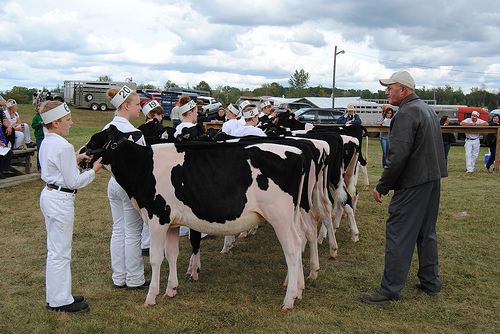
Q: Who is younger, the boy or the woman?
A: The boy is younger than the woman.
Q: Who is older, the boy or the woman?
A: The woman is older than the boy.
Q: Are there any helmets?
A: No, there are no helmets.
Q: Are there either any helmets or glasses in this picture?
A: No, there are no helmets or glasses.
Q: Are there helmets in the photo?
A: No, there are no helmets.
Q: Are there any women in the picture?
A: Yes, there is a woman.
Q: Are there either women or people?
A: Yes, there is a woman.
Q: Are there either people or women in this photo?
A: Yes, there is a woman.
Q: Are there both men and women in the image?
A: Yes, there are both a woman and a man.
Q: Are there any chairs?
A: No, there are no chairs.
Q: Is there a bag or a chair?
A: No, there are no chairs or bags.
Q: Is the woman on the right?
A: Yes, the woman is on the right of the image.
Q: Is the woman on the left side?
A: No, the woman is on the right of the image.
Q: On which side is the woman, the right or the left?
A: The woman is on the right of the image.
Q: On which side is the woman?
A: The woman is on the right of the image.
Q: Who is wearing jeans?
A: The woman is wearing jeans.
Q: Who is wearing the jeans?
A: The woman is wearing jeans.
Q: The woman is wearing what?
A: The woman is wearing jeans.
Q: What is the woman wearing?
A: The woman is wearing jeans.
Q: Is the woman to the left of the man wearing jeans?
A: Yes, the woman is wearing jeans.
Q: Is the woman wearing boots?
A: No, the woman is wearing jeans.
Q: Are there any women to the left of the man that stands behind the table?
A: Yes, there is a woman to the left of the man.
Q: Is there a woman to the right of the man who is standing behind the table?
A: No, the woman is to the left of the man.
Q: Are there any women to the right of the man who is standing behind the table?
A: No, the woman is to the left of the man.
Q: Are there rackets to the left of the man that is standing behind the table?
A: No, there is a woman to the left of the man.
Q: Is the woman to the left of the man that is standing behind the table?
A: Yes, the woman is to the left of the man.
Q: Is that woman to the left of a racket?
A: No, the woman is to the left of the man.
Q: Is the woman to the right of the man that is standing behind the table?
A: No, the woman is to the left of the man.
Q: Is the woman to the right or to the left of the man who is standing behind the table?
A: The woman is to the left of the man.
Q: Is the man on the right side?
A: Yes, the man is on the right of the image.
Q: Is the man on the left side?
A: No, the man is on the right of the image.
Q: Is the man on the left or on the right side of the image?
A: The man is on the right of the image.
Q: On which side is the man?
A: The man is on the right of the image.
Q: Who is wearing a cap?
A: The man is wearing a cap.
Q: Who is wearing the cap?
A: The man is wearing a cap.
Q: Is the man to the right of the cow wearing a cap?
A: Yes, the man is wearing a cap.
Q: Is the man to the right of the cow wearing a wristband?
A: No, the man is wearing a cap.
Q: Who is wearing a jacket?
A: The man is wearing a jacket.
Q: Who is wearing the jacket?
A: The man is wearing a jacket.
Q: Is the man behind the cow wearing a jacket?
A: Yes, the man is wearing a jacket.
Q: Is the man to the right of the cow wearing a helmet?
A: No, the man is wearing a jacket.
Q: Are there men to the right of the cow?
A: Yes, there is a man to the right of the cow.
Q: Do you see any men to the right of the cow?
A: Yes, there is a man to the right of the cow.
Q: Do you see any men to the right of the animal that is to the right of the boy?
A: Yes, there is a man to the right of the cow.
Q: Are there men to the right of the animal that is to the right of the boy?
A: Yes, there is a man to the right of the cow.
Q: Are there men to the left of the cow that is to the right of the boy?
A: No, the man is to the right of the cow.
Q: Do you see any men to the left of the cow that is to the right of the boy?
A: No, the man is to the right of the cow.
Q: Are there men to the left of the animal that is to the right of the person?
A: No, the man is to the right of the cow.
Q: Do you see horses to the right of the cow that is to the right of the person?
A: No, there is a man to the right of the cow.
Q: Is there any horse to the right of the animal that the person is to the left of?
A: No, there is a man to the right of the cow.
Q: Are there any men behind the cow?
A: Yes, there is a man behind the cow.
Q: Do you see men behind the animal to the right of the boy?
A: Yes, there is a man behind the cow.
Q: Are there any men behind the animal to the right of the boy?
A: Yes, there is a man behind the cow.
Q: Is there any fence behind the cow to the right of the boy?
A: No, there is a man behind the cow.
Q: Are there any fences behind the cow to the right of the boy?
A: No, there is a man behind the cow.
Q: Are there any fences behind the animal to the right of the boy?
A: No, there is a man behind the cow.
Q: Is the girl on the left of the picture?
A: Yes, the girl is on the left of the image.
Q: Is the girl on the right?
A: No, the girl is on the left of the image.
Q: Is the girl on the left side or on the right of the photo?
A: The girl is on the left of the image.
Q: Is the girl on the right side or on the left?
A: The girl is on the left of the image.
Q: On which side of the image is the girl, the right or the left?
A: The girl is on the left of the image.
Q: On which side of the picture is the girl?
A: The girl is on the left of the image.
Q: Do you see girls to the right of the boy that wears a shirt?
A: Yes, there is a girl to the right of the boy.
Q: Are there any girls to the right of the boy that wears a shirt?
A: Yes, there is a girl to the right of the boy.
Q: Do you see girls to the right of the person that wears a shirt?
A: Yes, there is a girl to the right of the boy.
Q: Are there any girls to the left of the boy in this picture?
A: No, the girl is to the right of the boy.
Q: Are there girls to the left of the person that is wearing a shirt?
A: No, the girl is to the right of the boy.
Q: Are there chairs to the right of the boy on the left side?
A: No, there is a girl to the right of the boy.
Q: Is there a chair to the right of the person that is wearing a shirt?
A: No, there is a girl to the right of the boy.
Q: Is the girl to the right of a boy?
A: Yes, the girl is to the right of a boy.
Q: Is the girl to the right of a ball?
A: No, the girl is to the right of a boy.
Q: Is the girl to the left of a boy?
A: No, the girl is to the right of a boy.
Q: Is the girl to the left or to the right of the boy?
A: The girl is to the right of the boy.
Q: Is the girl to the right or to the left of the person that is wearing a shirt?
A: The girl is to the right of the boy.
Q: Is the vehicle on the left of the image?
A: Yes, the vehicle is on the left of the image.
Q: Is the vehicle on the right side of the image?
A: No, the vehicle is on the left of the image.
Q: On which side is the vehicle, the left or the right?
A: The vehicle is on the left of the image.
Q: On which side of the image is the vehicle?
A: The vehicle is on the left of the image.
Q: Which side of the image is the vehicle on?
A: The vehicle is on the left of the image.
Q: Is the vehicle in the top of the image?
A: Yes, the vehicle is in the top of the image.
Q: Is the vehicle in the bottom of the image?
A: No, the vehicle is in the top of the image.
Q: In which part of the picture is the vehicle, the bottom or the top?
A: The vehicle is in the top of the image.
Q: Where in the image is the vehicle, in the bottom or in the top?
A: The vehicle is in the top of the image.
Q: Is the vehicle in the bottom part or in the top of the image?
A: The vehicle is in the top of the image.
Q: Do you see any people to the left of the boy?
A: Yes, there is a person to the left of the boy.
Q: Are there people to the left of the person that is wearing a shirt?
A: Yes, there is a person to the left of the boy.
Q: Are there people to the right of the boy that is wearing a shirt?
A: No, the person is to the left of the boy.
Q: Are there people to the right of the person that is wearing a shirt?
A: No, the person is to the left of the boy.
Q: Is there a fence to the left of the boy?
A: No, there is a person to the left of the boy.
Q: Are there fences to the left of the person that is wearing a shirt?
A: No, there is a person to the left of the boy.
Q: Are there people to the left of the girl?
A: Yes, there is a person to the left of the girl.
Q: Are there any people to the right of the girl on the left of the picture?
A: No, the person is to the left of the girl.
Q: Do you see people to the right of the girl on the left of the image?
A: No, the person is to the left of the girl.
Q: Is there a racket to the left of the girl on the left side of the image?
A: No, there is a person to the left of the girl.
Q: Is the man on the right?
A: Yes, the man is on the right of the image.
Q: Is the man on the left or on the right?
A: The man is on the right of the image.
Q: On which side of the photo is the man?
A: The man is on the right of the image.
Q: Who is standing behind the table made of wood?
A: The man is standing behind the table.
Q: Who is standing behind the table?
A: The man is standing behind the table.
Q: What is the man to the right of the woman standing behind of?
A: The man is standing behind the table.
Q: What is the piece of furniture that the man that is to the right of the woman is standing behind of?
A: The piece of furniture is a table.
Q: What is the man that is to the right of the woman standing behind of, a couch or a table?
A: The man is standing behind a table.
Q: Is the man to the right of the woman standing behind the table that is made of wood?
A: Yes, the man is standing behind the table.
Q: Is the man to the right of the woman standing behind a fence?
A: No, the man is standing behind the table.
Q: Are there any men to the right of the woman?
A: Yes, there is a man to the right of the woman.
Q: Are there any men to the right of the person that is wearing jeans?
A: Yes, there is a man to the right of the woman.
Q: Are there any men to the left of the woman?
A: No, the man is to the right of the woman.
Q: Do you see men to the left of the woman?
A: No, the man is to the right of the woman.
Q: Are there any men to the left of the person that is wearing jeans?
A: No, the man is to the right of the woman.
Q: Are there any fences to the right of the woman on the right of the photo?
A: No, there is a man to the right of the woman.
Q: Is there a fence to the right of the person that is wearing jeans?
A: No, there is a man to the right of the woman.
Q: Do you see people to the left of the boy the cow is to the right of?
A: Yes, there is a person to the left of the boy.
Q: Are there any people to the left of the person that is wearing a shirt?
A: Yes, there is a person to the left of the boy.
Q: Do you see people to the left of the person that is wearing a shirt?
A: Yes, there is a person to the left of the boy.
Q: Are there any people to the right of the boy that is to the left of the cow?
A: No, the person is to the left of the boy.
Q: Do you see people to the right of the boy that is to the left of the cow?
A: No, the person is to the left of the boy.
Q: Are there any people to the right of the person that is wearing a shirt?
A: No, the person is to the left of the boy.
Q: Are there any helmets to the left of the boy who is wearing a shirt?
A: No, there is a person to the left of the boy.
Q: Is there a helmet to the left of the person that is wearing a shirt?
A: No, there is a person to the left of the boy.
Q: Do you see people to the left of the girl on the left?
A: Yes, there is a person to the left of the girl.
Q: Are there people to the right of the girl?
A: No, the person is to the left of the girl.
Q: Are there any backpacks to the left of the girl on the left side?
A: No, there is a person to the left of the girl.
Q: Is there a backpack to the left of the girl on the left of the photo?
A: No, there is a person to the left of the girl.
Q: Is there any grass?
A: Yes, there is grass.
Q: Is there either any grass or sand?
A: Yes, there is grass.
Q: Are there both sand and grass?
A: No, there is grass but no sand.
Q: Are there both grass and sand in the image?
A: No, there is grass but no sand.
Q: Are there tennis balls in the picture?
A: No, there are no tennis balls.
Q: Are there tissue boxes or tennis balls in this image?
A: No, there are no tennis balls or tissue boxes.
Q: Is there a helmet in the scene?
A: No, there are no helmets.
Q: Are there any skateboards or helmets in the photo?
A: No, there are no helmets or skateboards.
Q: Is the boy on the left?
A: Yes, the boy is on the left of the image.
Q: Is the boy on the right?
A: No, the boy is on the left of the image.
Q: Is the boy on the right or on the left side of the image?
A: The boy is on the left of the image.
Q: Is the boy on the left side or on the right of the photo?
A: The boy is on the left of the image.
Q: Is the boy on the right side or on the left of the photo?
A: The boy is on the left of the image.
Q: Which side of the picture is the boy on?
A: The boy is on the left of the image.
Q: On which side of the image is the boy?
A: The boy is on the left of the image.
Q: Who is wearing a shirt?
A: The boy is wearing a shirt.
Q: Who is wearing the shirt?
A: The boy is wearing a shirt.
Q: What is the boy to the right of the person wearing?
A: The boy is wearing a shirt.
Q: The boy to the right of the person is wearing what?
A: The boy is wearing a shirt.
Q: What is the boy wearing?
A: The boy is wearing a shirt.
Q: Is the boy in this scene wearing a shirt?
A: Yes, the boy is wearing a shirt.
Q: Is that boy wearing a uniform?
A: No, the boy is wearing a shirt.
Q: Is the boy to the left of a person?
A: No, the boy is to the right of a person.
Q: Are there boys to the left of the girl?
A: Yes, there is a boy to the left of the girl.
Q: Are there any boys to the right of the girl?
A: No, the boy is to the left of the girl.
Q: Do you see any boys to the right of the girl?
A: No, the boy is to the left of the girl.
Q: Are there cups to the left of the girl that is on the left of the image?
A: No, there is a boy to the left of the girl.